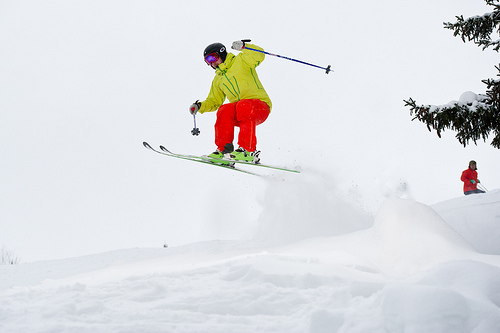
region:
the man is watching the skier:
[462, 156, 482, 195]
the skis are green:
[169, 146, 291, 183]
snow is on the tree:
[412, 87, 489, 141]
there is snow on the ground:
[237, 228, 425, 332]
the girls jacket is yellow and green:
[212, 59, 262, 121]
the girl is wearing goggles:
[201, 56, 218, 63]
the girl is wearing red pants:
[215, 106, 263, 152]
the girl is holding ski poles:
[248, 39, 347, 74]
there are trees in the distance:
[0, 250, 17, 267]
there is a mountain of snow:
[248, 170, 393, 260]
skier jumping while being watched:
[115, 22, 491, 218]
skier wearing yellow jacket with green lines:
[185, 30, 295, 115]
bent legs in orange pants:
[166, 90, 291, 170]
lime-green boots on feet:
[195, 141, 275, 176]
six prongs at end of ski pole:
[180, 121, 205, 136]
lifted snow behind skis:
[196, 120, 442, 270]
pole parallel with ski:
[220, 21, 345, 171]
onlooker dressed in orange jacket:
[425, 135, 487, 210]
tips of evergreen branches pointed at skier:
[205, 16, 490, 156]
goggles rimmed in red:
[191, 43, 226, 76]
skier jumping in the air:
[132, 25, 353, 184]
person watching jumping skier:
[457, 152, 491, 200]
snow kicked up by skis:
[263, 167, 379, 245]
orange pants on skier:
[203, 97, 275, 162]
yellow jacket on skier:
[198, 40, 276, 112]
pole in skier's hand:
[240, 39, 344, 76]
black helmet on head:
[204, 38, 229, 58]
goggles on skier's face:
[203, 53, 222, 69]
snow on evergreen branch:
[406, 86, 496, 129]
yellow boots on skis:
[205, 144, 258, 169]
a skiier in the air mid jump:
[92, 9, 369, 236]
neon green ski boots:
[198, 145, 269, 176]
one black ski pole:
[233, 41, 349, 85]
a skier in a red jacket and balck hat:
[440, 150, 495, 211]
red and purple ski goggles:
[196, 50, 225, 66]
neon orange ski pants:
[204, 95, 288, 160]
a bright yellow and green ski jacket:
[175, 43, 292, 118]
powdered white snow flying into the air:
[257, 157, 401, 239]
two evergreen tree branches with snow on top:
[389, 2, 497, 155]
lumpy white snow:
[39, 270, 187, 331]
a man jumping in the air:
[152, 32, 313, 183]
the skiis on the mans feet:
[133, 142, 300, 181]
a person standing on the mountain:
[458, 155, 471, 191]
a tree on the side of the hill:
[389, 9, 499, 145]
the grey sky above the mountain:
[2, 7, 466, 219]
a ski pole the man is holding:
[221, 33, 350, 88]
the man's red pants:
[208, 98, 258, 132]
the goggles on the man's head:
[191, 48, 223, 65]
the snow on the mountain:
[26, 202, 489, 332]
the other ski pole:
[187, 107, 203, 135]